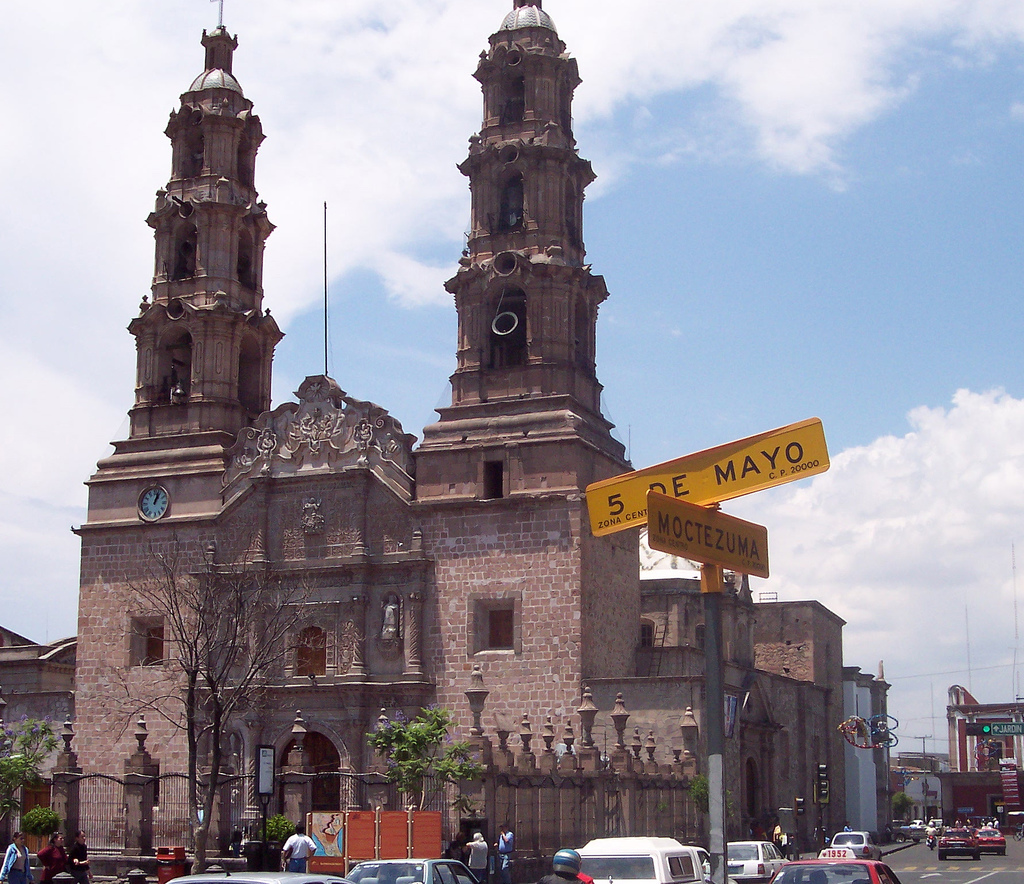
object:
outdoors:
[0, 12, 1022, 873]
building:
[840, 664, 898, 839]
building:
[939, 683, 1020, 830]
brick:
[90, 660, 114, 668]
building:
[68, 5, 843, 847]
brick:
[147, 721, 167, 729]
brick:
[140, 553, 152, 561]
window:
[469, 588, 515, 657]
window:
[484, 462, 505, 501]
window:
[298, 622, 327, 674]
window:
[131, 617, 161, 665]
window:
[488, 288, 527, 366]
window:
[495, 174, 525, 235]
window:
[562, 182, 582, 243]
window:
[501, 69, 521, 118]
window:
[184, 133, 201, 171]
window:
[169, 222, 196, 283]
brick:
[487, 690, 502, 703]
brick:
[498, 533, 508, 540]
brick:
[514, 547, 523, 556]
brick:
[544, 552, 566, 560]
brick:
[577, 594, 594, 611]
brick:
[521, 690, 531, 701]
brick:
[88, 660, 101, 666]